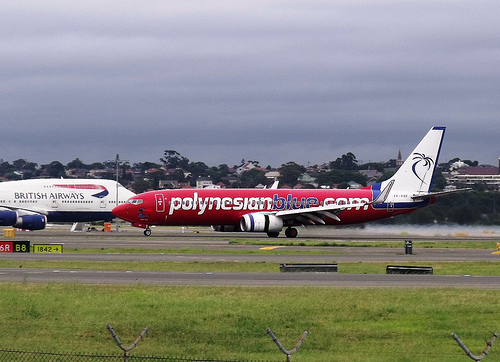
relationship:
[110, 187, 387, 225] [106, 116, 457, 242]
body of plane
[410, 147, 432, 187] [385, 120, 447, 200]
logo painted on tail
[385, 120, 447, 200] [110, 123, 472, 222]
tail of plane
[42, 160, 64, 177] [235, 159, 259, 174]
tree and house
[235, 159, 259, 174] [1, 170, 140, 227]
house behind airplane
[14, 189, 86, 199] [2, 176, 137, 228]
lettering on airplane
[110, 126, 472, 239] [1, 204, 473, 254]
airplane parked on a landing strip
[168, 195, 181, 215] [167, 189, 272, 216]
letter reading polynesian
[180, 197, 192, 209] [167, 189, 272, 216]
letter reading polynesian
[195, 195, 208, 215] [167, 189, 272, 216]
letter reading polynesian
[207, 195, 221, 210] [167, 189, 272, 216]
letter reading polynesian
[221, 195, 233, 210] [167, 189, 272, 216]
letter reading polynesian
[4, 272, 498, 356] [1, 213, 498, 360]
grass on an airfield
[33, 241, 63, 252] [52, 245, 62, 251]
sign with an arrow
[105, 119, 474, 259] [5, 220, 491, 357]
airplane on ground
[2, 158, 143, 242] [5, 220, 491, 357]
airplane on ground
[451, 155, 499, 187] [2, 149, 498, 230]
building in background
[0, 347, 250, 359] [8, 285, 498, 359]
barbed fence in forefront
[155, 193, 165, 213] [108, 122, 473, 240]
door in airplane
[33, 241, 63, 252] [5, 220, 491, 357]
sign on ground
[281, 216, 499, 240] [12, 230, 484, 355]
white smoke on ground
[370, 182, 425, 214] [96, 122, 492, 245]
stripe on plane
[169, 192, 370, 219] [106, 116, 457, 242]
lettering on plane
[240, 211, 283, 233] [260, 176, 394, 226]
engine under wing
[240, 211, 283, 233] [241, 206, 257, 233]
engine has stripe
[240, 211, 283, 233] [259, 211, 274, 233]
engine has stripe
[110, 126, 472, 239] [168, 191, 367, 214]
airplane has logo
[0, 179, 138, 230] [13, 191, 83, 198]
airplane has logo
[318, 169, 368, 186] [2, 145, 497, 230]
distant tree in distance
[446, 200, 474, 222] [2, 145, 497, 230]
distant tree in distance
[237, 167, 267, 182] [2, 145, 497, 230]
distant tree in distance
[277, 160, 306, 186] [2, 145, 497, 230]
distant tree in distance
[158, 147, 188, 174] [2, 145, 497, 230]
distant tree in distance